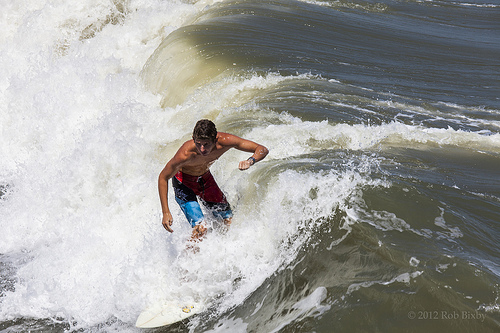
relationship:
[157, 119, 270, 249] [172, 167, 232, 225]
person wearing shorts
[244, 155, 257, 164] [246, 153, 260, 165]
band around wrist